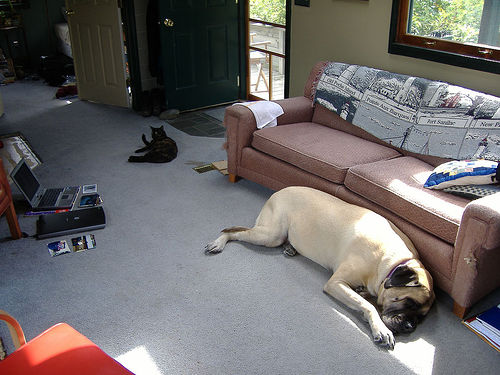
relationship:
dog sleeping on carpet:
[205, 186, 435, 351] [0, 78, 498, 374]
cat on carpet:
[128, 125, 178, 161] [0, 78, 498, 374]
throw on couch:
[311, 60, 499, 162] [222, 60, 499, 318]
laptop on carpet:
[10, 157, 81, 208] [0, 78, 498, 374]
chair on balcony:
[248, 33, 273, 94] [249, 24, 285, 101]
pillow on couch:
[423, 160, 499, 191] [222, 60, 499, 318]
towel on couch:
[233, 101, 285, 130] [222, 60, 499, 318]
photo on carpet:
[47, 241, 71, 257] [0, 78, 498, 374]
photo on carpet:
[72, 233, 97, 252] [0, 78, 498, 374]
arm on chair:
[1, 311, 23, 348] [1, 313, 135, 374]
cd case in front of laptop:
[79, 193, 98, 208] [10, 157, 81, 208]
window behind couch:
[388, 0, 499, 76] [222, 60, 499, 318]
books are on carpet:
[461, 302, 500, 352] [0, 78, 498, 374]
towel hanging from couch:
[233, 101, 285, 130] [222, 60, 499, 318]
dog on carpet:
[205, 186, 435, 351] [0, 78, 498, 374]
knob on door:
[163, 17, 174, 27] [156, 0, 240, 113]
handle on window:
[421, 39, 436, 47] [388, 0, 499, 76]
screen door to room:
[244, 0, 286, 102] [1, 1, 499, 373]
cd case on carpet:
[79, 193, 98, 208] [0, 78, 498, 374]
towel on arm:
[233, 101, 285, 130] [224, 97, 314, 182]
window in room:
[388, 0, 499, 76] [1, 1, 499, 373]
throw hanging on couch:
[311, 60, 499, 162] [222, 60, 499, 318]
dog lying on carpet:
[205, 186, 435, 351] [0, 78, 498, 374]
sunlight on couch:
[385, 168, 499, 224] [222, 60, 499, 318]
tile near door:
[164, 101, 226, 139] [156, 0, 240, 113]